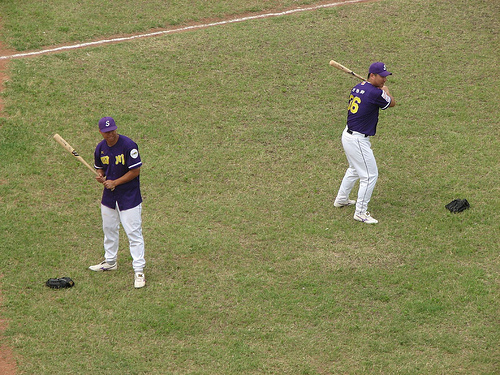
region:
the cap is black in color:
[97, 113, 117, 135]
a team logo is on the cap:
[103, 119, 113, 129]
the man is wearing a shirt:
[96, 134, 143, 208]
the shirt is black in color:
[98, 134, 143, 206]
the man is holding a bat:
[50, 126, 147, 203]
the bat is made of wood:
[51, 130, 107, 187]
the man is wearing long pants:
[101, 189, 151, 270]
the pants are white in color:
[101, 200, 143, 267]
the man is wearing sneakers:
[91, 259, 146, 290]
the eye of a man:
[100, 124, 125, 152]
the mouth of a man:
[100, 123, 134, 148]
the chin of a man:
[95, 103, 149, 162]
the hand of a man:
[102, 170, 122, 201]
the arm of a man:
[116, 118, 169, 192]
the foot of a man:
[119, 248, 183, 300]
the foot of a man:
[80, 243, 127, 290]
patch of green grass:
[228, 290, 278, 319]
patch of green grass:
[102, 325, 142, 358]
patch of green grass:
[277, 319, 313, 356]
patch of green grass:
[344, 327, 386, 358]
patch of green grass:
[226, 304, 261, 332]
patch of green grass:
[134, 320, 158, 347]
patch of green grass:
[232, 319, 280, 348]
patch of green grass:
[396, 322, 435, 357]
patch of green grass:
[250, 301, 305, 333]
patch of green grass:
[192, 329, 232, 369]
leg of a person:
[88, 202, 125, 287]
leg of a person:
[118, 207, 157, 267]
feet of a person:
[88, 262, 120, 284]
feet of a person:
[131, 268, 171, 298]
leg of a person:
[353, 150, 397, 204]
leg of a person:
[333, 167, 365, 200]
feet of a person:
[328, 196, 368, 208]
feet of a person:
[348, 207, 394, 227]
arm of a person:
[376, 76, 396, 113]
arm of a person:
[109, 154, 137, 192]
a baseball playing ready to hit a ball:
[328, 56, 395, 227]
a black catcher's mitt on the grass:
[446, 193, 471, 214]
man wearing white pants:
[338, 125, 380, 208]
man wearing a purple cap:
[96, 116, 118, 133]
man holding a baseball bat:
[53, 133, 115, 192]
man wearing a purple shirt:
[93, 135, 143, 210]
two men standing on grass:
[54, 57, 396, 291]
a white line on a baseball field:
[3, 0, 358, 65]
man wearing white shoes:
[336, 198, 379, 225]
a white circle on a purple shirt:
[130, 146, 139, 158]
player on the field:
[283, 26, 452, 219]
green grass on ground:
[219, 205, 331, 294]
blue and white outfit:
[46, 103, 178, 288]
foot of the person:
[111, 250, 182, 312]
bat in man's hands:
[35, 123, 105, 200]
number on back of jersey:
[326, 87, 375, 122]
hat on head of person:
[356, 47, 408, 84]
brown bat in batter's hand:
[48, 129, 118, 196]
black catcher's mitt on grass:
[42, 273, 79, 295]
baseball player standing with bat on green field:
[45, 112, 152, 291]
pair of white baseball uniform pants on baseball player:
[332, 122, 382, 219]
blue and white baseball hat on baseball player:
[94, 113, 119, 138]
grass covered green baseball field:
[0, 1, 499, 373]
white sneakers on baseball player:
[85, 255, 147, 292]